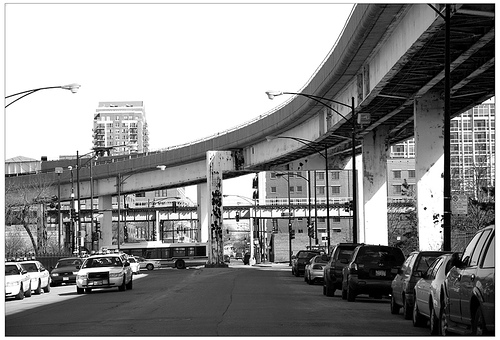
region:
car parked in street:
[288, 247, 313, 275]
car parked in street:
[303, 250, 325, 282]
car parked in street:
[323, 242, 360, 293]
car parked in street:
[342, 233, 399, 300]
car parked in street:
[385, 248, 436, 310]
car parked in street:
[406, 253, 454, 323]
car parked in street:
[432, 217, 497, 333]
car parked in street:
[0, 262, 35, 295]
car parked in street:
[23, 255, 51, 292]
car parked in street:
[50, 250, 89, 287]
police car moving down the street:
[71, 242, 150, 295]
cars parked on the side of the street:
[333, 233, 468, 315]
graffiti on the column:
[210, 176, 222, 252]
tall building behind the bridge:
[82, 91, 147, 151]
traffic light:
[231, 202, 242, 219]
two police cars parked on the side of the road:
[10, 250, 62, 301]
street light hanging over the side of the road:
[16, 70, 85, 117]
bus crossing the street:
[125, 237, 204, 267]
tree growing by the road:
[446, 191, 498, 244]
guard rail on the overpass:
[234, 197, 279, 204]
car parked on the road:
[6, 253, 48, 318]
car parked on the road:
[22, 259, 56, 296]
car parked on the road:
[48, 250, 83, 290]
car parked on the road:
[444, 220, 493, 333]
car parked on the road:
[409, 241, 460, 322]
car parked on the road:
[386, 242, 434, 310]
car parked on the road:
[337, 237, 403, 301]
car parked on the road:
[317, 231, 349, 290]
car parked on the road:
[306, 252, 328, 284]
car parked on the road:
[289, 246, 311, 273]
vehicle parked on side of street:
[441, 221, 496, 332]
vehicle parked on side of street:
[408, 253, 453, 330]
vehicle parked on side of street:
[382, 246, 441, 317]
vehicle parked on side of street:
[340, 244, 405, 299]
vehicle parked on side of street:
[318, 238, 356, 297]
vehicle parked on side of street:
[296, 253, 326, 285]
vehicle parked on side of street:
[286, 246, 315, 279]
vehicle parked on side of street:
[5, 256, 33, 298]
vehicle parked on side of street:
[19, 256, 58, 294]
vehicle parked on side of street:
[51, 249, 83, 282]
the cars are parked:
[269, 207, 494, 337]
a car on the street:
[71, 240, 131, 298]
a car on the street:
[68, 235, 175, 318]